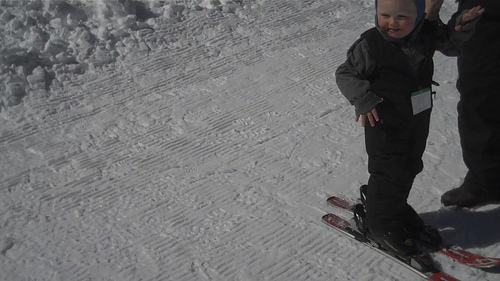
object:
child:
[333, 0, 485, 260]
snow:
[0, 0, 500, 281]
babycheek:
[376, 17, 386, 29]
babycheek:
[398, 21, 414, 28]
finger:
[370, 108, 380, 123]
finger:
[366, 112, 376, 127]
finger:
[361, 113, 366, 127]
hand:
[352, 97, 383, 127]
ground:
[0, 0, 500, 281]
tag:
[409, 87, 432, 117]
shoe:
[440, 184, 500, 211]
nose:
[387, 15, 401, 27]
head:
[374, 0, 421, 40]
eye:
[379, 13, 391, 18]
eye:
[397, 14, 408, 20]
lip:
[387, 29, 402, 33]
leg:
[363, 115, 419, 228]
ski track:
[0, 4, 376, 145]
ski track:
[286, 198, 335, 224]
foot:
[362, 220, 417, 256]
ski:
[320, 212, 459, 281]